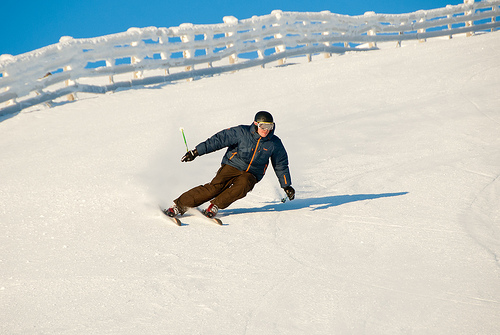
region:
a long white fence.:
[8, 11, 492, 91]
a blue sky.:
[3, 0, 90, 39]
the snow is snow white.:
[27, 230, 463, 323]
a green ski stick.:
[176, 122, 195, 161]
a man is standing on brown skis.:
[145, 214, 235, 231]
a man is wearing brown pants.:
[194, 175, 246, 209]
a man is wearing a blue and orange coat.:
[216, 136, 271, 173]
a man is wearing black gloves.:
[255, 117, 275, 130]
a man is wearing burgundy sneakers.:
[165, 200, 226, 216]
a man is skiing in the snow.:
[41, 67, 446, 291]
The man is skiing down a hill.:
[126, 60, 346, 257]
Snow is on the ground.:
[51, 245, 421, 316]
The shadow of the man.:
[205, 166, 420, 241]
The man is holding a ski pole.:
[161, 98, 201, 164]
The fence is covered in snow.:
[0, 0, 497, 97]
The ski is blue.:
[26, 3, 116, 26]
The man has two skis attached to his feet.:
[158, 182, 253, 247]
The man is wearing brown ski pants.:
[160, 148, 256, 219]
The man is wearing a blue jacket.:
[187, 102, 303, 193]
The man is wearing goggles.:
[242, 118, 287, 133]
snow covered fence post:
[96, 29, 118, 96]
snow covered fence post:
[121, 19, 148, 88]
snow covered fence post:
[149, 23, 177, 83]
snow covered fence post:
[177, 27, 204, 79]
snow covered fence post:
[200, 20, 221, 80]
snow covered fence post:
[216, 17, 238, 73]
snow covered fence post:
[246, 14, 270, 70]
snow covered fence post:
[268, 12, 290, 66]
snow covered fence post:
[290, 5, 315, 63]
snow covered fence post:
[336, 15, 354, 55]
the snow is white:
[211, 238, 326, 326]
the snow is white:
[352, 198, 377, 328]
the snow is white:
[337, 330, 342, 334]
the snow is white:
[350, 298, 387, 333]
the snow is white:
[340, 228, 381, 322]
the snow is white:
[334, 281, 365, 333]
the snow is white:
[328, 274, 346, 304]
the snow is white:
[360, 294, 381, 328]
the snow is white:
[301, 241, 395, 328]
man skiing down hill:
[167, 117, 322, 237]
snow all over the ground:
[38, 140, 493, 320]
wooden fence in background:
[10, 0, 488, 96]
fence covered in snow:
[2, 0, 477, 85]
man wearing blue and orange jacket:
[150, 96, 320, 216]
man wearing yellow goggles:
[246, 105, 292, 142]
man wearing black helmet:
[248, 101, 288, 141]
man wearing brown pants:
[146, 160, 271, 223]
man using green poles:
[160, 115, 310, 213]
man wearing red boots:
[151, 187, 250, 239]